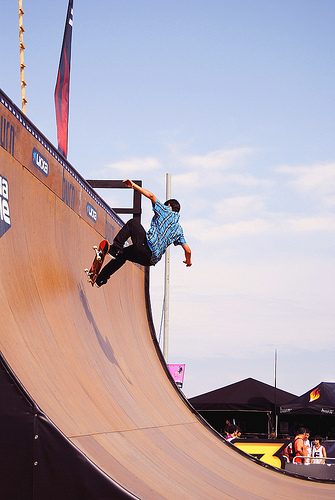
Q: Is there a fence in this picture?
A: No, there are no fences.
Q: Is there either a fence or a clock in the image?
A: No, there are no fences or clocks.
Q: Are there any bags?
A: No, there are no bags.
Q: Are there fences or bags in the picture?
A: No, there are no bags or fences.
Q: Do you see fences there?
A: No, there are no fences.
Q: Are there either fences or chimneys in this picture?
A: No, there are no fences or chimneys.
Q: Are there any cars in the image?
A: No, there are no cars.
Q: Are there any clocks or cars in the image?
A: No, there are no cars or clocks.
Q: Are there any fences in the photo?
A: No, there are no fences.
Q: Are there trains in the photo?
A: No, there are no trains.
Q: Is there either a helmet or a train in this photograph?
A: No, there are no trains or helmets.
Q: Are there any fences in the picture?
A: No, there are no fences.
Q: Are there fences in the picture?
A: No, there are no fences.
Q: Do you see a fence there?
A: No, there are no fences.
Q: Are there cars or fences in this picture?
A: No, there are no fences or cars.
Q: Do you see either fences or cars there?
A: No, there are no fences or cars.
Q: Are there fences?
A: No, there are no fences.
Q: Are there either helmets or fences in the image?
A: No, there are no fences or helmets.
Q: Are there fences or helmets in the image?
A: No, there are no fences or helmets.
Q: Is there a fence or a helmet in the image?
A: No, there are no fences or helmets.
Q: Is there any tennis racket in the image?
A: No, there are no rackets.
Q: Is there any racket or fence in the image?
A: No, there are no rackets or fences.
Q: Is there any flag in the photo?
A: Yes, there is a flag.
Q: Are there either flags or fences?
A: Yes, there is a flag.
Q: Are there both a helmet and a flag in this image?
A: No, there is a flag but no helmets.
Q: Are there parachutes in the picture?
A: No, there are no parachutes.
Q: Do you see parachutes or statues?
A: No, there are no parachutes or statues.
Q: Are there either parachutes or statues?
A: No, there are no parachutes or statues.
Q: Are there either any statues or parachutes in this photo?
A: No, there are no parachutes or statues.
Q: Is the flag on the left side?
A: Yes, the flag is on the left of the image.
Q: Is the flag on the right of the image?
A: No, the flag is on the left of the image.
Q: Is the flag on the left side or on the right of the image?
A: The flag is on the left of the image.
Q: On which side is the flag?
A: The flag is on the left of the image.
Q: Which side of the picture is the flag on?
A: The flag is on the left of the image.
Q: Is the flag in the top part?
A: Yes, the flag is in the top of the image.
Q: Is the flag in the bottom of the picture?
A: No, the flag is in the top of the image.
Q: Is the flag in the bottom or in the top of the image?
A: The flag is in the top of the image.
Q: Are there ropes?
A: No, there are no ropes.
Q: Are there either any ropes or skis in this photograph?
A: No, there are no ropes or skis.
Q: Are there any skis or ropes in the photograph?
A: No, there are no ropes or skis.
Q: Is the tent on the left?
A: No, the tent is on the right of the image.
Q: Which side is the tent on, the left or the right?
A: The tent is on the right of the image.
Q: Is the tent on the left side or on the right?
A: The tent is on the right of the image.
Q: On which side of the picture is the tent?
A: The tent is on the right of the image.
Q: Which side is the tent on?
A: The tent is on the right of the image.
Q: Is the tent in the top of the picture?
A: No, the tent is in the bottom of the image.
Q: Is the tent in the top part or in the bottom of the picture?
A: The tent is in the bottom of the image.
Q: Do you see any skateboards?
A: Yes, there is a skateboard.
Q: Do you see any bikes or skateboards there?
A: Yes, there is a skateboard.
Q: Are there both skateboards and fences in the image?
A: No, there is a skateboard but no fences.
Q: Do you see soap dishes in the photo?
A: No, there are no soap dishes.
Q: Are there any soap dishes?
A: No, there are no soap dishes.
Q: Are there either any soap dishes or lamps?
A: No, there are no soap dishes or lamps.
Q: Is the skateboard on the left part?
A: Yes, the skateboard is on the left of the image.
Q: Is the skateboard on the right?
A: No, the skateboard is on the left of the image.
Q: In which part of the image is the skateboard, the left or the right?
A: The skateboard is on the left of the image.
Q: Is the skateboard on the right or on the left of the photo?
A: The skateboard is on the left of the image.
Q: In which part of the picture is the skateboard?
A: The skateboard is on the left of the image.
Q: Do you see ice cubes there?
A: No, there are no ice cubes.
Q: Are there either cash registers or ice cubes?
A: No, there are no ice cubes or cash registers.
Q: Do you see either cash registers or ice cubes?
A: No, there are no ice cubes or cash registers.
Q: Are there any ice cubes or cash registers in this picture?
A: No, there are no ice cubes or cash registers.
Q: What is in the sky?
A: The clouds are in the sky.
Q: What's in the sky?
A: The clouds are in the sky.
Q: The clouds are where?
A: The clouds are in the sky.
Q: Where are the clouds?
A: The clouds are in the sky.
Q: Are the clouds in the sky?
A: Yes, the clouds are in the sky.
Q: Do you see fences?
A: No, there are no fences.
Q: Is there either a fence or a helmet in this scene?
A: No, there are no fences or helmets.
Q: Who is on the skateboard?
A: The boy is on the skateboard.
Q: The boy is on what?
A: The boy is on the skateboard.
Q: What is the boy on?
A: The boy is on the skateboard.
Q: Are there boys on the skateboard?
A: Yes, there is a boy on the skateboard.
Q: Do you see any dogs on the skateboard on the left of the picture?
A: No, there is a boy on the skateboard.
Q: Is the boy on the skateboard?
A: Yes, the boy is on the skateboard.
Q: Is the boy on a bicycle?
A: No, the boy is on the skateboard.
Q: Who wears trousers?
A: The boy wears trousers.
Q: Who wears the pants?
A: The boy wears trousers.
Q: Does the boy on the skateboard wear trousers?
A: Yes, the boy wears trousers.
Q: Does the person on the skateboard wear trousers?
A: Yes, the boy wears trousers.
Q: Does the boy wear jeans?
A: No, the boy wears trousers.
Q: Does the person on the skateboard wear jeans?
A: No, the boy wears trousers.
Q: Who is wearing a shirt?
A: The boy is wearing a shirt.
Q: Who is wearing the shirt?
A: The boy is wearing a shirt.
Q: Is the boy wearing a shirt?
A: Yes, the boy is wearing a shirt.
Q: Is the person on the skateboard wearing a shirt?
A: Yes, the boy is wearing a shirt.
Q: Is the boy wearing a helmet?
A: No, the boy is wearing a shirt.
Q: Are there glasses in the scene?
A: No, there are no glasses.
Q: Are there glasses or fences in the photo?
A: No, there are no glasses or fences.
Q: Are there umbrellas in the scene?
A: No, there are no umbrellas.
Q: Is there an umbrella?
A: No, there are no umbrellas.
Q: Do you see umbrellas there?
A: No, there are no umbrellas.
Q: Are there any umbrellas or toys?
A: No, there are no umbrellas or toys.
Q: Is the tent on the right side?
A: Yes, the tent is on the right of the image.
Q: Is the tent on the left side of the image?
A: No, the tent is on the right of the image.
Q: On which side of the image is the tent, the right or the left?
A: The tent is on the right of the image.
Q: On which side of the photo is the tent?
A: The tent is on the right of the image.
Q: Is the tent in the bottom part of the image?
A: Yes, the tent is in the bottom of the image.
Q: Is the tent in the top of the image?
A: No, the tent is in the bottom of the image.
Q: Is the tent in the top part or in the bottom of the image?
A: The tent is in the bottom of the image.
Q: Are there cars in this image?
A: No, there are no cars.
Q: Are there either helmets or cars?
A: No, there are no cars or helmets.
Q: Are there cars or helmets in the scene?
A: No, there are no cars or helmets.